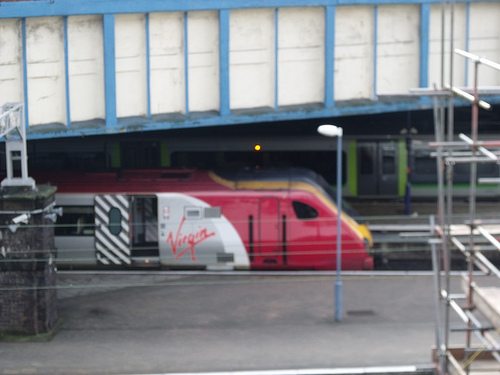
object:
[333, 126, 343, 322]
pole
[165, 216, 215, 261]
name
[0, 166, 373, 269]
car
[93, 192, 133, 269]
door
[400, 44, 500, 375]
scaffolding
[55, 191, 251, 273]
car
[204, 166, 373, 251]
stripe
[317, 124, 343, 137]
light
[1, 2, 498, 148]
overpass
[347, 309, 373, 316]
vent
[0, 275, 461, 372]
ground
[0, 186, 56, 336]
brick post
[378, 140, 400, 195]
door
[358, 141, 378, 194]
door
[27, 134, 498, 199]
train